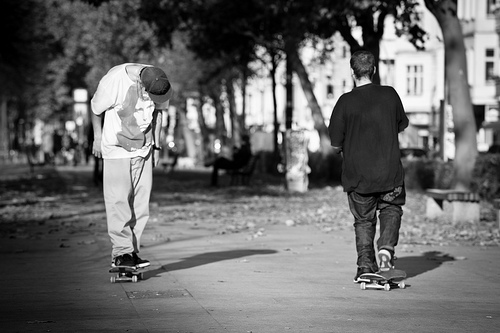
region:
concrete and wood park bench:
[418, 179, 485, 229]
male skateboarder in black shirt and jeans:
[323, 49, 417, 297]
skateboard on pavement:
[353, 263, 415, 295]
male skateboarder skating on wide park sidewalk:
[83, 51, 180, 285]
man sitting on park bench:
[199, 125, 264, 192]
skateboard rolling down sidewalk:
[106, 253, 151, 285]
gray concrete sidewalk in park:
[2, 142, 498, 331]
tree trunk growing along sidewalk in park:
[418, 0, 480, 232]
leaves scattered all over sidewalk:
[1, 174, 498, 249]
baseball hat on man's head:
[138, 66, 177, 111]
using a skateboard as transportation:
[353, 265, 416, 293]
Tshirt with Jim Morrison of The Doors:
[112, 85, 161, 152]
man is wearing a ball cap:
[135, 63, 180, 110]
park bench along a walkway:
[415, 182, 492, 232]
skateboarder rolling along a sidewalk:
[88, 57, 174, 287]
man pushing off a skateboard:
[316, 37, 433, 298]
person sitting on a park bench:
[198, 130, 270, 189]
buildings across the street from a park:
[386, 3, 497, 173]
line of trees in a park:
[7, 3, 327, 191]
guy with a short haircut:
[339, 43, 382, 90]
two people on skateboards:
[84, 45, 451, 306]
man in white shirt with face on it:
[90, 47, 181, 161]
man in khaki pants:
[94, 150, 164, 255]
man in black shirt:
[321, 72, 409, 196]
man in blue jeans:
[325, 188, 415, 273]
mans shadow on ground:
[47, 47, 261, 331]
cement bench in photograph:
[430, 180, 498, 234]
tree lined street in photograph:
[0, 8, 477, 185]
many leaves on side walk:
[27, 161, 495, 283]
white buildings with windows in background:
[231, 55, 498, 167]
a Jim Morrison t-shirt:
[91, 62, 154, 156]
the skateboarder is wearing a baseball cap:
[141, 67, 173, 104]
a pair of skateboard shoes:
[111, 253, 140, 269]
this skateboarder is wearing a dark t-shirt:
[328, 83, 410, 191]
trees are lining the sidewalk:
[175, 0, 332, 191]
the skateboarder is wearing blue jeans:
[347, 186, 407, 268]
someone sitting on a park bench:
[205, 133, 265, 189]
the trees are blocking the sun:
[0, 161, 97, 208]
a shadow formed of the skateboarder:
[151, 246, 281, 277]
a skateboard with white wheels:
[360, 271, 408, 291]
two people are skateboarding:
[84, 54, 411, 304]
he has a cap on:
[139, 64, 184, 111]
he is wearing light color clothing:
[76, 65, 174, 267]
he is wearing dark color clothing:
[323, 82, 415, 272]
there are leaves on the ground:
[159, 184, 349, 252]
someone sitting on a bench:
[207, 128, 256, 182]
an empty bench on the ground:
[422, 184, 482, 227]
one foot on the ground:
[348, 262, 381, 282]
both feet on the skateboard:
[104, 253, 155, 284]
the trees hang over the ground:
[4, 0, 426, 72]